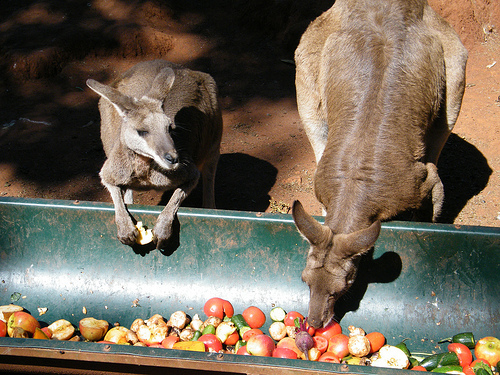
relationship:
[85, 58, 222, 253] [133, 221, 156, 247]
kangaroo has fruit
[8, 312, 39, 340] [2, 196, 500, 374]
fruit in tub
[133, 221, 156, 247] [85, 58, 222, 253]
fruit for kangaroo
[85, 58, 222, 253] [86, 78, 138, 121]
kangaroo has ears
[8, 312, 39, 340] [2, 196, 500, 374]
fruit are in tub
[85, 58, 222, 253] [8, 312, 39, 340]
kangaroo above fruit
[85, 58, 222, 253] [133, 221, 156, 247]
kangaroo holding fruit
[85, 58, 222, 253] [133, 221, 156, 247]
kangaroo eating fruit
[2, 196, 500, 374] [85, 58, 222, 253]
tub for kangaroo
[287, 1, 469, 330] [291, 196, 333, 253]
kangaroo has ears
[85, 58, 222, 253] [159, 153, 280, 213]
kangaroo has shadow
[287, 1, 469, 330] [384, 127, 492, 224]
kangaroo has shadow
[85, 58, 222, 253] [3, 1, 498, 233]
kangaroo standing on dirt